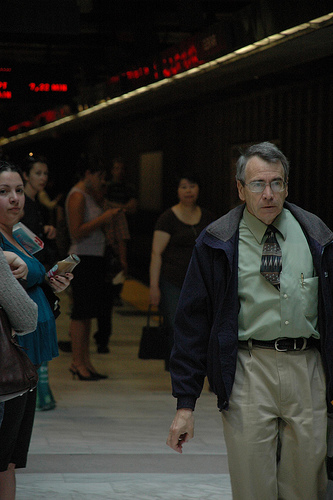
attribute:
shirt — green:
[239, 216, 318, 341]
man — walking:
[211, 147, 321, 254]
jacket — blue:
[165, 230, 261, 409]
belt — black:
[240, 332, 331, 358]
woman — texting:
[49, 151, 128, 256]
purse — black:
[137, 302, 170, 360]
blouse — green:
[5, 228, 70, 380]